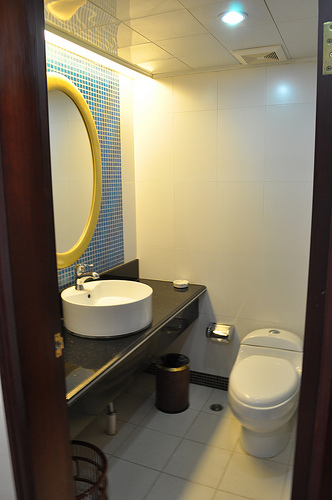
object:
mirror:
[46, 71, 103, 267]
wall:
[35, 33, 134, 291]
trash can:
[155, 351, 191, 415]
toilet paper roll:
[212, 328, 228, 339]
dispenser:
[205, 321, 234, 346]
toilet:
[225, 324, 302, 459]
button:
[265, 327, 278, 335]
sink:
[56, 274, 156, 339]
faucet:
[74, 264, 101, 290]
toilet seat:
[229, 353, 297, 406]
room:
[2, 0, 331, 496]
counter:
[59, 279, 205, 437]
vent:
[228, 42, 286, 68]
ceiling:
[34, 2, 319, 74]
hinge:
[319, 20, 331, 79]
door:
[285, 2, 331, 497]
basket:
[68, 438, 109, 497]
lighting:
[40, 31, 152, 83]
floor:
[65, 372, 300, 496]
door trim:
[0, 3, 72, 497]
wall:
[134, 60, 320, 347]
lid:
[159, 352, 189, 370]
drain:
[208, 402, 223, 414]